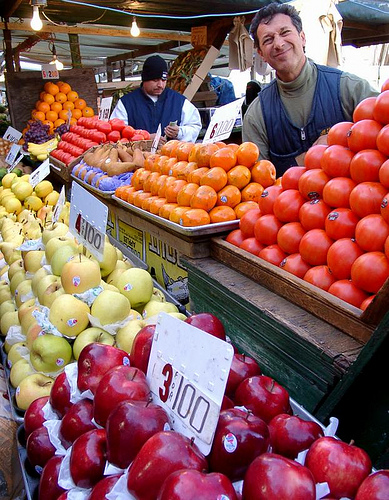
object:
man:
[239, 0, 377, 178]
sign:
[143, 307, 235, 458]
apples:
[155, 468, 238, 499]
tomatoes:
[348, 250, 388, 291]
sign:
[67, 178, 108, 262]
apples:
[67, 425, 105, 484]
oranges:
[80, 106, 96, 116]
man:
[110, 53, 202, 149]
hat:
[139, 52, 170, 81]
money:
[167, 125, 180, 138]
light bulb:
[129, 14, 141, 39]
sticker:
[121, 355, 131, 364]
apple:
[77, 341, 134, 395]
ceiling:
[0, 0, 388, 38]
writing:
[156, 363, 210, 439]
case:
[210, 232, 388, 343]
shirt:
[241, 60, 379, 167]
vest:
[256, 64, 345, 176]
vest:
[117, 88, 185, 143]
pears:
[0, 215, 13, 231]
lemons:
[3, 196, 19, 217]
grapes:
[21, 117, 69, 142]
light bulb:
[28, 6, 43, 32]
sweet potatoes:
[107, 161, 135, 176]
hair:
[247, 1, 302, 49]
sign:
[40, 60, 60, 78]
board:
[5, 67, 100, 139]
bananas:
[31, 137, 61, 156]